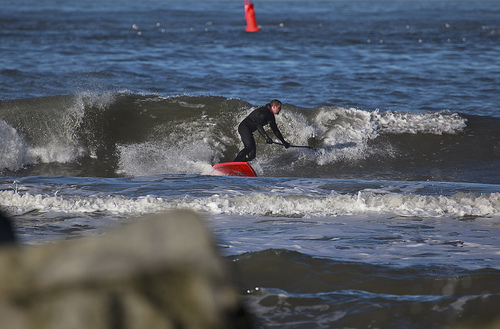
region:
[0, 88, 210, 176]
A Sea Wave cresting towards the shore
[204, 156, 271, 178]
A Red Surf Board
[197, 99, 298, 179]
A Surfer coming in with the wave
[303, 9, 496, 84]
A large body of water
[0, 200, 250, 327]
A blurry Rocky boulder in the foreground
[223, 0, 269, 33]
A floating buoy in the water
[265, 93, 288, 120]
The Surfer's head resting on his shoulders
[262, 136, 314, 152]
A pole of some kind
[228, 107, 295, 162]
A Black Surfer Suit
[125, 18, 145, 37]
Sea Birds Floating in the water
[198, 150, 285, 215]
red wakeboard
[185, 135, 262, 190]
red wakeboard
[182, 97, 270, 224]
red wakeboard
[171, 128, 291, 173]
red wakeboard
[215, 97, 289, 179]
surfer in black wetsuit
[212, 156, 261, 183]
red surfboard on water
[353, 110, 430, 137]
white cap on crashing wave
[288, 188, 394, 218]
white foam of moving water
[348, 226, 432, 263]
white seafoam on water surface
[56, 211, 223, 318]
blurry rock in foreground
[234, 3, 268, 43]
red buoy in water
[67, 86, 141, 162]
curl in crashing wave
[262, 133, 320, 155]
pole in surfers hand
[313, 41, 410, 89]
ripples on water surface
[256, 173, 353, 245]
the water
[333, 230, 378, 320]
the water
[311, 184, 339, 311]
the water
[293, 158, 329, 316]
the water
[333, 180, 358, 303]
the water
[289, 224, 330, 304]
the water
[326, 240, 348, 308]
the water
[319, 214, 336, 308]
the water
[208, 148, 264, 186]
red long surf board